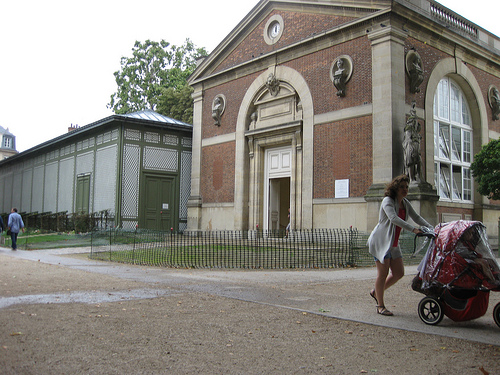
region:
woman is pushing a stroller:
[315, 140, 491, 357]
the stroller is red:
[400, 190, 492, 330]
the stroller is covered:
[397, 197, 495, 318]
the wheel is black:
[401, 285, 448, 330]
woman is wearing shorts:
[350, 237, 409, 299]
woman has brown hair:
[363, 168, 417, 210]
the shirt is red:
[372, 194, 413, 245]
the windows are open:
[415, 104, 474, 206]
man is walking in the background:
[0, 202, 47, 270]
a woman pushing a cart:
[360, 173, 497, 327]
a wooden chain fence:
[155, 228, 357, 264]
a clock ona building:
[260, 18, 282, 43]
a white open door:
[262, 148, 303, 240]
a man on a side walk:
[5, 208, 26, 257]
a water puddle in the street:
[7, 279, 160, 313]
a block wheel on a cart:
[418, 293, 446, 323]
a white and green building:
[0, 131, 186, 231]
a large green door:
[139, 174, 177, 235]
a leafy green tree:
[111, 40, 212, 114]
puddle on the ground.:
[82, 290, 144, 310]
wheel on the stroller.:
[416, 298, 440, 326]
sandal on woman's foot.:
[370, 305, 390, 320]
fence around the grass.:
[273, 239, 313, 252]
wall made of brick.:
[318, 126, 361, 169]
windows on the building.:
[433, 95, 456, 122]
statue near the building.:
[403, 115, 418, 172]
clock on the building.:
[267, 20, 282, 38]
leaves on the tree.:
[165, 67, 178, 92]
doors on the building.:
[77, 182, 87, 209]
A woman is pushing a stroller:
[369, 161, 486, 322]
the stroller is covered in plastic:
[413, 217, 486, 362]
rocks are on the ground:
[80, 269, 295, 342]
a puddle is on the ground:
[15, 270, 206, 313]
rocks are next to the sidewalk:
[148, 250, 327, 362]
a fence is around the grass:
[81, 222, 346, 372]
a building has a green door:
[63, 155, 316, 257]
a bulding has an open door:
[245, 137, 425, 248]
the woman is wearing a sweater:
[369, 175, 480, 276]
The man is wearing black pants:
[3, 205, 86, 302]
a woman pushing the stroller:
[350, 160, 497, 347]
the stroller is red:
[398, 200, 484, 348]